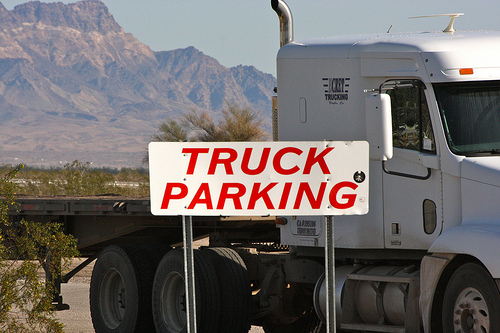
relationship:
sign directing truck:
[148, 140, 368, 217] [0, 0, 498, 330]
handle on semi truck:
[389, 220, 401, 238] [3, 0, 497, 332]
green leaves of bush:
[10, 215, 44, 237] [1, 206, 74, 331]